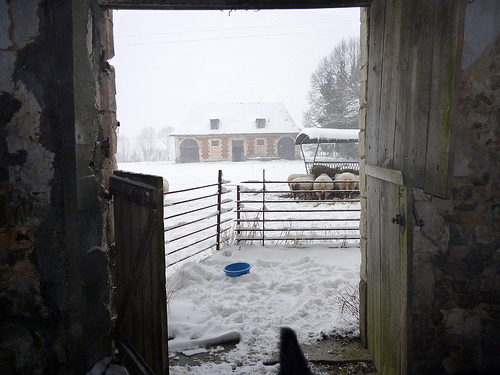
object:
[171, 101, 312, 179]
home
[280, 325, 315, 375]
stone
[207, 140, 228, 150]
window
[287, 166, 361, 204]
animals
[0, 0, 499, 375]
barn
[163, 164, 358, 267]
fencing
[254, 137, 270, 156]
door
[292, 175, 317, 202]
sheep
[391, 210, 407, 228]
knob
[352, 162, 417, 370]
door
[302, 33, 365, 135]
tree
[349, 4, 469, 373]
door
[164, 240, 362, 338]
ground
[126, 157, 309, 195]
ground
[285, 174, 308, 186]
sheep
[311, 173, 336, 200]
sheep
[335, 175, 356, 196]
sheep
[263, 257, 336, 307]
tracks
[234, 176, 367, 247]
fence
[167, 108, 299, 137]
roof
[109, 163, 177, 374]
door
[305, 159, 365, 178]
hay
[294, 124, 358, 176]
troft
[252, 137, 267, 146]
window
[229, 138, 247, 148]
window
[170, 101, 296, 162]
building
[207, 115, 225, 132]
window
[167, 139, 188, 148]
window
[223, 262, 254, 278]
bowl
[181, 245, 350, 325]
snow